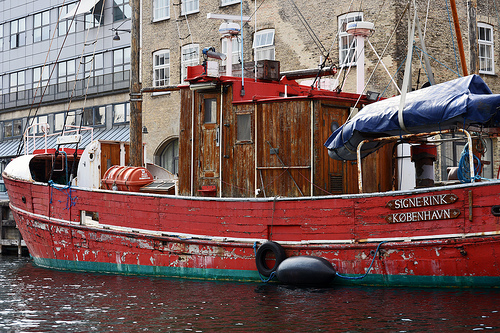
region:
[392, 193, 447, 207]
white writing on boat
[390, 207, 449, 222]
white writing on boat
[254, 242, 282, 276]
black wheel on boat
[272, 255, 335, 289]
black float by boat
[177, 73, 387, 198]
wood cabin on boat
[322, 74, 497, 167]
blue tarp on boat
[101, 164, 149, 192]
orange barrel on boat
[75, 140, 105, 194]
white front of boat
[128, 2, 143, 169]
wood pole on boat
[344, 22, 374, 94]
white pole on boat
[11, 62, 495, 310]
an old wooden boat dock on the side of the river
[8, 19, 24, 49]
a window on the side of a building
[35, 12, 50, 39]
a window on the side of a building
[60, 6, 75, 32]
a window on the side of a building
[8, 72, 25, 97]
a window on the side of a building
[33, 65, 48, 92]
a window on the side of a building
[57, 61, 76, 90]
a window on the side of a building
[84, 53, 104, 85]
a window on the side of a building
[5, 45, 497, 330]
boat in the water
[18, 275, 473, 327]
water near the boat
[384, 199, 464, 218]
name on the boat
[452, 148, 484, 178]
ropes on the boat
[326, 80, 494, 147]
covering on the boat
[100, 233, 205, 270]
worn paint on the boat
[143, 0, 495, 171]
building behind the boat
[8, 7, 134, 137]
building behind the boat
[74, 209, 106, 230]
hole in the side of boat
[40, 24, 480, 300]
A boat in the water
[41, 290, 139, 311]
The water is still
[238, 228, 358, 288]
Black object against the boat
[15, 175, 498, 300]
The boat is red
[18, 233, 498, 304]
Green wood at bottom of the baot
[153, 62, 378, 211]
This is dark brown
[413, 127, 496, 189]
One person in the shot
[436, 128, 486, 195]
Person is driving the boat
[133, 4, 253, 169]
This building is made of bricks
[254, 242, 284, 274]
black tire on side of the boat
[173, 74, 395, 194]
brown wooden cabin on the boat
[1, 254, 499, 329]
body of water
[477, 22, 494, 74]
window on the building to the right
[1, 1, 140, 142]
large gray building with many windows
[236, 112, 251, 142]
small window in the cabin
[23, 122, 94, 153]
white railing on the boat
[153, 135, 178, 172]
curved doorway on a building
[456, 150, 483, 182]
blue hose wrapped on a pole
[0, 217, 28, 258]
wooden fence next to the boat